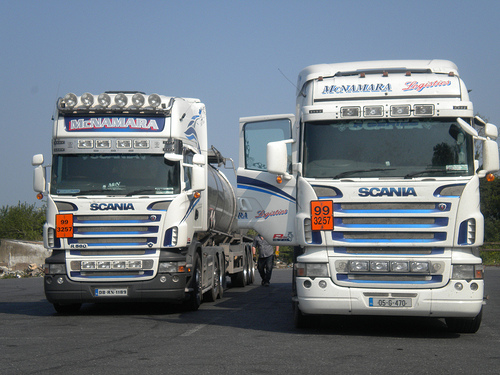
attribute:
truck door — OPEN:
[233, 112, 303, 246]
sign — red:
[305, 195, 338, 234]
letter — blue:
[370, 187, 380, 197]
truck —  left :
[45, 85, 233, 317]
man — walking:
[247, 240, 282, 290]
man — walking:
[247, 222, 281, 284]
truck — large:
[239, 60, 498, 309]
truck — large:
[268, 67, 499, 335]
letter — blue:
[371, 186, 380, 196]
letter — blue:
[351, 182, 421, 198]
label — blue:
[358, 185, 415, 198]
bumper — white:
[291, 255, 485, 317]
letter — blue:
[125, 202, 135, 210]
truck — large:
[30, 89, 256, 320]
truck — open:
[296, 66, 486, 331]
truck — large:
[234, 56, 498, 339]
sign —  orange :
[300, 180, 350, 275]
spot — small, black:
[390, 344, 410, 354]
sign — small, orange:
[304, 195, 339, 237]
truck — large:
[28, 76, 245, 327]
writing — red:
[390, 69, 448, 93]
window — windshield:
[302, 122, 471, 165]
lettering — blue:
[357, 180, 419, 195]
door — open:
[237, 111, 301, 245]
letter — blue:
[358, 185, 370, 197]